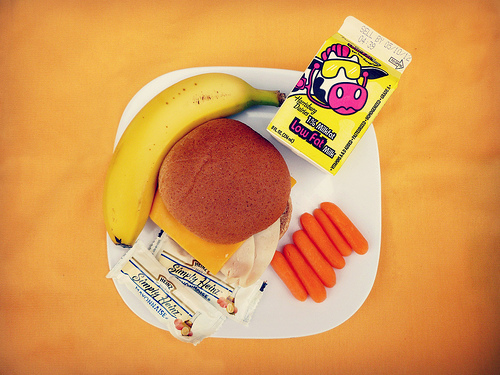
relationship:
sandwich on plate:
[156, 120, 293, 286] [108, 64, 382, 341]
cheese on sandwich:
[149, 190, 246, 276] [156, 120, 293, 286]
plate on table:
[108, 64, 382, 341] [1, 2, 500, 373]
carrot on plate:
[318, 202, 370, 257] [108, 64, 382, 341]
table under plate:
[1, 2, 500, 373] [108, 64, 382, 341]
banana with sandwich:
[106, 71, 286, 249] [156, 120, 293, 286]